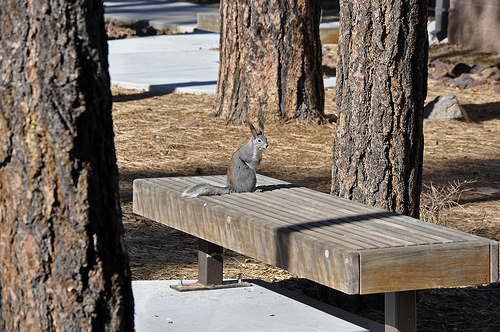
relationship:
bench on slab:
[255, 181, 484, 291] [150, 289, 326, 327]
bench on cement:
[255, 181, 484, 291] [158, 294, 289, 324]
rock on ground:
[429, 92, 460, 118] [432, 122, 479, 139]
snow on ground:
[325, 18, 339, 33] [432, 122, 479, 139]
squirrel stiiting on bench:
[233, 134, 267, 196] [255, 181, 484, 291]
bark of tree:
[35, 106, 85, 153] [6, 3, 120, 323]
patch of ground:
[149, 108, 184, 124] [432, 122, 479, 139]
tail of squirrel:
[180, 180, 227, 196] [233, 134, 267, 196]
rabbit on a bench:
[233, 134, 267, 196] [255, 181, 484, 291]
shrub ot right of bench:
[428, 175, 465, 217] [255, 181, 484, 291]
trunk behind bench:
[342, 5, 425, 193] [255, 181, 484, 291]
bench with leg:
[255, 181, 484, 291] [387, 293, 418, 324]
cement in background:
[114, 35, 220, 89] [108, 36, 217, 90]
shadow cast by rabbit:
[259, 180, 286, 196] [233, 134, 267, 196]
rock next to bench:
[429, 92, 460, 118] [255, 181, 484, 291]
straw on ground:
[444, 146, 473, 158] [432, 122, 479, 139]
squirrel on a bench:
[233, 134, 267, 196] [255, 181, 484, 291]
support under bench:
[387, 293, 418, 324] [255, 181, 484, 291]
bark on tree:
[35, 106, 85, 153] [6, 3, 120, 323]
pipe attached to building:
[430, 1, 447, 46] [450, 2, 499, 41]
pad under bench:
[142, 289, 240, 331] [255, 181, 484, 291]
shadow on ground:
[423, 158, 493, 176] [432, 122, 479, 139]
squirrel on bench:
[233, 134, 267, 196] [255, 181, 484, 291]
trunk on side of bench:
[50, 145, 109, 267] [255, 181, 484, 291]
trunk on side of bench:
[342, 5, 425, 193] [255, 181, 484, 291]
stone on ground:
[429, 92, 460, 118] [432, 122, 479, 139]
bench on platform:
[255, 181, 484, 291] [158, 294, 289, 324]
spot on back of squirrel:
[227, 157, 237, 186] [233, 134, 267, 196]